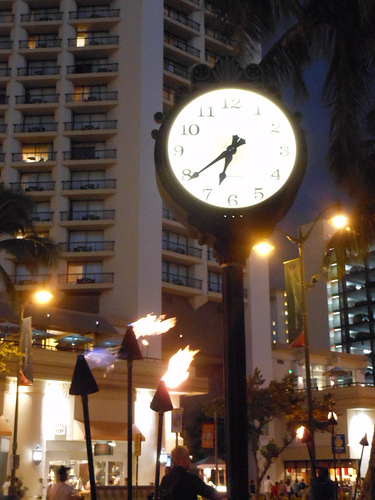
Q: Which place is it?
A: It is a shopping center.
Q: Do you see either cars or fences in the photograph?
A: No, there are no cars or fences.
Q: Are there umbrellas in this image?
A: Yes, there is an umbrella.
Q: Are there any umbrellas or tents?
A: Yes, there is an umbrella.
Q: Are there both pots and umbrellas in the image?
A: No, there is an umbrella but no pots.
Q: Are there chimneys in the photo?
A: No, there are no chimneys.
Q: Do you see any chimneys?
A: No, there are no chimneys.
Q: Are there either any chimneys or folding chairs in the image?
A: No, there are no chimneys or folding chairs.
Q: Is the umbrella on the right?
A: No, the umbrella is on the left of the image.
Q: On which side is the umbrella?
A: The umbrella is on the left of the image.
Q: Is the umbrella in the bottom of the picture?
A: Yes, the umbrella is in the bottom of the image.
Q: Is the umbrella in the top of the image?
A: No, the umbrella is in the bottom of the image.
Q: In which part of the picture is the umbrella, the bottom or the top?
A: The umbrella is in the bottom of the image.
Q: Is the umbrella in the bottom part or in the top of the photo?
A: The umbrella is in the bottom of the image.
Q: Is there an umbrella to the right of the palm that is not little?
A: Yes, there is an umbrella to the right of the palm tree.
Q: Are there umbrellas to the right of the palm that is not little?
A: Yes, there is an umbrella to the right of the palm tree.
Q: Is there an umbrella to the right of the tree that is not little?
A: Yes, there is an umbrella to the right of the palm tree.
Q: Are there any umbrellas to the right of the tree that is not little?
A: Yes, there is an umbrella to the right of the palm tree.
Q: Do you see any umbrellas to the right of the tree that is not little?
A: Yes, there is an umbrella to the right of the palm tree.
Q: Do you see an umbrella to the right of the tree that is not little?
A: Yes, there is an umbrella to the right of the palm tree.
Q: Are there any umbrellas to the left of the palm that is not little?
A: No, the umbrella is to the right of the palm tree.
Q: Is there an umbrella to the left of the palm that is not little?
A: No, the umbrella is to the right of the palm tree.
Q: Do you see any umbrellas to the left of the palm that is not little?
A: No, the umbrella is to the right of the palm tree.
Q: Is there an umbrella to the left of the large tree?
A: No, the umbrella is to the right of the palm tree.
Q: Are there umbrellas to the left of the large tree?
A: No, the umbrella is to the right of the palm tree.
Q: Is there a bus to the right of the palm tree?
A: No, there is an umbrella to the right of the palm tree.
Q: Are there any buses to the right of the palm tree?
A: No, there is an umbrella to the right of the palm tree.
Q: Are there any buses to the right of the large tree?
A: No, there is an umbrella to the right of the palm tree.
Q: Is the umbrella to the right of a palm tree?
A: Yes, the umbrella is to the right of a palm tree.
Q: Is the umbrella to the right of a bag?
A: No, the umbrella is to the right of a palm tree.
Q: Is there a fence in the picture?
A: No, there are no fences.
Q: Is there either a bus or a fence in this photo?
A: No, there are no fences or buses.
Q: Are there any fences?
A: No, there are no fences.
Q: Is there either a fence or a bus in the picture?
A: No, there are no fences or buses.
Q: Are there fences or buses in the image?
A: No, there are no fences or buses.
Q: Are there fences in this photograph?
A: No, there are no fences.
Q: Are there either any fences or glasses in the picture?
A: No, there are no fences or glasses.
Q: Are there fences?
A: No, there are no fences.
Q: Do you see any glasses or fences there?
A: No, there are no fences or glasses.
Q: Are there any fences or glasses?
A: No, there are no fences or glasses.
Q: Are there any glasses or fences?
A: No, there are no fences or glasses.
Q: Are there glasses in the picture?
A: No, there are no glasses.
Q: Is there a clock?
A: Yes, there is a clock.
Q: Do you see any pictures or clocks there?
A: Yes, there is a clock.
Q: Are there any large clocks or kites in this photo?
A: Yes, there is a large clock.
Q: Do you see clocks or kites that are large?
A: Yes, the clock is large.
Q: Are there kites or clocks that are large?
A: Yes, the clock is large.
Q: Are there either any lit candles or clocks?
A: Yes, there is a lit clock.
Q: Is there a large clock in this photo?
A: Yes, there is a large clock.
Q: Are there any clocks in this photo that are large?
A: Yes, there is a clock that is large.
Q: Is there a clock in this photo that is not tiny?
A: Yes, there is a large clock.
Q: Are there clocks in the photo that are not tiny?
A: Yes, there is a large clock.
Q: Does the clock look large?
A: Yes, the clock is large.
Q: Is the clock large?
A: Yes, the clock is large.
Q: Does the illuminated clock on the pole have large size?
A: Yes, the clock is large.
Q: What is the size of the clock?
A: The clock is large.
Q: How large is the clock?
A: The clock is large.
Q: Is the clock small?
A: No, the clock is large.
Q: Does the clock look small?
A: No, the clock is large.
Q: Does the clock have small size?
A: No, the clock is large.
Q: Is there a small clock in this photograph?
A: No, there is a clock but it is large.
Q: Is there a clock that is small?
A: No, there is a clock but it is large.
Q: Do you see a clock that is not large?
A: No, there is a clock but it is large.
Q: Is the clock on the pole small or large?
A: The clock is large.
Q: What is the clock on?
A: The clock is on the pole.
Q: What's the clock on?
A: The clock is on the pole.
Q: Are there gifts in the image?
A: No, there are no gifts.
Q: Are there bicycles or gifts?
A: No, there are no gifts or bicycles.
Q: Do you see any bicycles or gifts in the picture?
A: No, there are no gifts or bicycles.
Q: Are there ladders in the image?
A: No, there are no ladders.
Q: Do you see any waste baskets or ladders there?
A: No, there are no ladders or waste baskets.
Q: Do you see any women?
A: Yes, there is a woman.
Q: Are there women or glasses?
A: Yes, there is a woman.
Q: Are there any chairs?
A: No, there are no chairs.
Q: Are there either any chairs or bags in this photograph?
A: No, there are no chairs or bags.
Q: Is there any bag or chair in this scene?
A: No, there are no chairs or bags.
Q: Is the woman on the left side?
A: Yes, the woman is on the left of the image.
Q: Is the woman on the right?
A: No, the woman is on the left of the image.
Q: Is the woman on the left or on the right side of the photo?
A: The woman is on the left of the image.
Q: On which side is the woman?
A: The woman is on the left of the image.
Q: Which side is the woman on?
A: The woman is on the left of the image.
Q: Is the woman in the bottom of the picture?
A: Yes, the woman is in the bottom of the image.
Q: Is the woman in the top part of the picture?
A: No, the woman is in the bottom of the image.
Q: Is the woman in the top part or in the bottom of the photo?
A: The woman is in the bottom of the image.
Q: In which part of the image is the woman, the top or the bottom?
A: The woman is in the bottom of the image.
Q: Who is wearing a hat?
A: The woman is wearing a hat.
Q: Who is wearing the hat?
A: The woman is wearing a hat.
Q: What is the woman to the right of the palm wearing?
A: The woman is wearing a hat.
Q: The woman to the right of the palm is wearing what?
A: The woman is wearing a hat.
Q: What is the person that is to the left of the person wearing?
A: The woman is wearing a hat.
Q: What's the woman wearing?
A: The woman is wearing a hat.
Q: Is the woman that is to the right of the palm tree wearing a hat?
A: Yes, the woman is wearing a hat.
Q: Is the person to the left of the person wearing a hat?
A: Yes, the woman is wearing a hat.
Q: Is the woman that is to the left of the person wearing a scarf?
A: No, the woman is wearing a hat.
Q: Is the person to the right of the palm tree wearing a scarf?
A: No, the woman is wearing a hat.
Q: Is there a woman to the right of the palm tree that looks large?
A: Yes, there is a woman to the right of the palm.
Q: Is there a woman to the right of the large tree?
A: Yes, there is a woman to the right of the palm.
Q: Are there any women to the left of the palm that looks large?
A: No, the woman is to the right of the palm.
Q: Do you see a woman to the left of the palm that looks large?
A: No, the woman is to the right of the palm.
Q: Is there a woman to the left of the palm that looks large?
A: No, the woman is to the right of the palm.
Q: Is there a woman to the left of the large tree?
A: No, the woman is to the right of the palm.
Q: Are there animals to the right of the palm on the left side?
A: No, there is a woman to the right of the palm.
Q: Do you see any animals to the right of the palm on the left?
A: No, there is a woman to the right of the palm.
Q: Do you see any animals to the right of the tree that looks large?
A: No, there is a woman to the right of the palm.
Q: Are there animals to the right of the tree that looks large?
A: No, there is a woman to the right of the palm.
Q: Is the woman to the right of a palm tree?
A: Yes, the woman is to the right of a palm tree.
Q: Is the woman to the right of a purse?
A: No, the woman is to the right of a palm tree.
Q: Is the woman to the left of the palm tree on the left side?
A: No, the woman is to the right of the palm.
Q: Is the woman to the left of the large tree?
A: No, the woman is to the right of the palm.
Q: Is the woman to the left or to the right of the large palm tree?
A: The woman is to the right of the palm.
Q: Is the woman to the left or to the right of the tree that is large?
A: The woman is to the right of the palm.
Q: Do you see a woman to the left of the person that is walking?
A: Yes, there is a woman to the left of the person.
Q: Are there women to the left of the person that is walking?
A: Yes, there is a woman to the left of the person.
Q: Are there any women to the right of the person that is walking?
A: No, the woman is to the left of the person.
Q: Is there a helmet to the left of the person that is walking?
A: No, there is a woman to the left of the person.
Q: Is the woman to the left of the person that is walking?
A: Yes, the woman is to the left of the person.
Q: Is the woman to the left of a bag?
A: No, the woman is to the left of the person.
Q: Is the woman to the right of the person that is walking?
A: No, the woman is to the left of the person.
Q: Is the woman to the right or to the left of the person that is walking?
A: The woman is to the left of the person.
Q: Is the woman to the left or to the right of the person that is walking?
A: The woman is to the left of the person.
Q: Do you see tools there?
A: No, there are no tools.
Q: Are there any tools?
A: No, there are no tools.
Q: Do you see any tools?
A: No, there are no tools.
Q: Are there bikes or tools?
A: No, there are no tools or bikes.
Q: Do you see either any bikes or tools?
A: No, there are no tools or bikes.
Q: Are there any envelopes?
A: No, there are no envelopes.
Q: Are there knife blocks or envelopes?
A: No, there are no envelopes or knife blocks.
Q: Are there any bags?
A: No, there are no bags.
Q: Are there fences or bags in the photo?
A: No, there are no bags or fences.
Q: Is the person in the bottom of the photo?
A: Yes, the person is in the bottom of the image.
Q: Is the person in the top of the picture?
A: No, the person is in the bottom of the image.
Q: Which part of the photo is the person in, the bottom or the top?
A: The person is in the bottom of the image.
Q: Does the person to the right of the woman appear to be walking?
A: Yes, the person is walking.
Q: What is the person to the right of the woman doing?
A: The person is walking.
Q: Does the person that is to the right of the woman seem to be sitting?
A: No, the person is walking.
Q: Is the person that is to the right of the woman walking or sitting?
A: The person is walking.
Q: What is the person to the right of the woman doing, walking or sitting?
A: The person is walking.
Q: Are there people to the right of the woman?
A: Yes, there is a person to the right of the woman.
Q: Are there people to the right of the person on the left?
A: Yes, there is a person to the right of the woman.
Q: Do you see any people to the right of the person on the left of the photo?
A: Yes, there is a person to the right of the woman.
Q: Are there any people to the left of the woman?
A: No, the person is to the right of the woman.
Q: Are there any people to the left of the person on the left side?
A: No, the person is to the right of the woman.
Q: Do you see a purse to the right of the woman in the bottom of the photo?
A: No, there is a person to the right of the woman.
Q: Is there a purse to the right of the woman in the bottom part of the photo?
A: No, there is a person to the right of the woman.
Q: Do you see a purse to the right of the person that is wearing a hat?
A: No, there is a person to the right of the woman.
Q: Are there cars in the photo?
A: No, there are no cars.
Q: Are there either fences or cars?
A: No, there are no cars or fences.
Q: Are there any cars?
A: No, there are no cars.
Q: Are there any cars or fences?
A: No, there are no cars or fences.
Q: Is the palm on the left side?
A: Yes, the palm is on the left of the image.